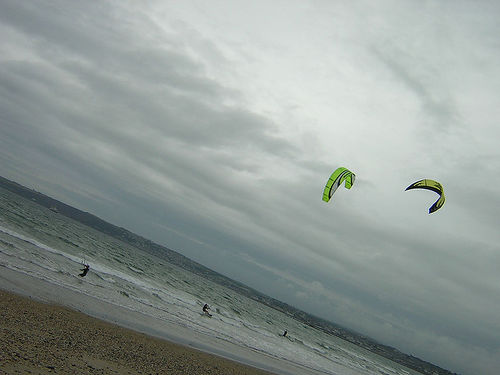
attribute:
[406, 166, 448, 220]
kite — blue, yellow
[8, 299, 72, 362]
sand — brown 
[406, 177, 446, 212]
kite — large, green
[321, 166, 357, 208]
kite — green, red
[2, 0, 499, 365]
sky — grey and white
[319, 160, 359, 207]
surf kite — large, green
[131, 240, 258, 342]
waves — white 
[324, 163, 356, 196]
parasail — green